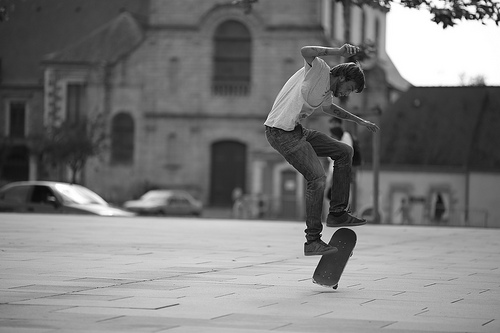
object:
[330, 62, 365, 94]
hair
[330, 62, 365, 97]
head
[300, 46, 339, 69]
arms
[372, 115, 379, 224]
pole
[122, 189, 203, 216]
car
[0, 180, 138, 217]
car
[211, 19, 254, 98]
window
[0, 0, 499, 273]
background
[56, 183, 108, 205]
windshield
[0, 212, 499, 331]
street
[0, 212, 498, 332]
walkway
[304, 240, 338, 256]
dark shoes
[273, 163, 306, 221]
door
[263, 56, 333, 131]
white shirt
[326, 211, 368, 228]
tennis shoes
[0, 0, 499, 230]
large building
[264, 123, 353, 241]
jeans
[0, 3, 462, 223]
windows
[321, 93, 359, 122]
arms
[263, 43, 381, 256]
man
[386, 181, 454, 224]
signs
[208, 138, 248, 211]
door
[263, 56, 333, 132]
shirt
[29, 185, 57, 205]
passenger window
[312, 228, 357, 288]
skateboard